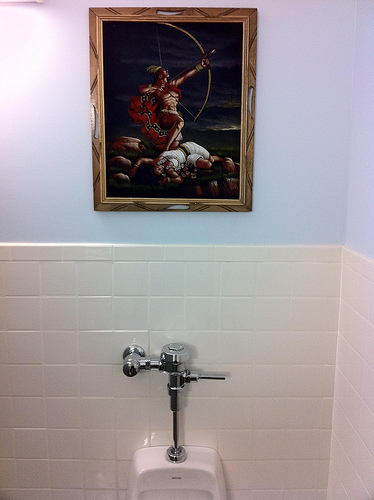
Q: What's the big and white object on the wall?
A: Urinal.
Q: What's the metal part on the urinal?
A: Flush handle.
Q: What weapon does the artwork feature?
A: Bow and arrow.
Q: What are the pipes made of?
A: Metal.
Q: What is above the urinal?
A: Picture.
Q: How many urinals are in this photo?
A: One.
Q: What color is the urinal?
A: White.